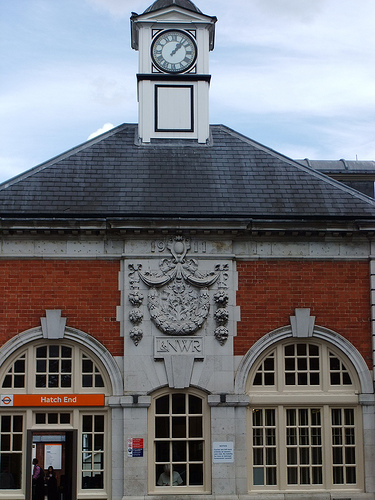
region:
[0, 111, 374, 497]
Red brick building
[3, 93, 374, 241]
Black tile roof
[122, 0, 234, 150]
White clock tower trimmed in black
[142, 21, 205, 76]
Clock face in the tower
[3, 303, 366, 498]
Arched windows trimmed in stone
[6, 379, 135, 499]
Entry way surrounded by glass windows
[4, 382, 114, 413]
Orange sign above the entrance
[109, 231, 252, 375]
Stone/concrete sculpture on the building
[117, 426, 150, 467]
Red, black, and white sign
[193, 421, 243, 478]
White sign on the building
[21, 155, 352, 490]
an old brick building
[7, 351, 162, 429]
an orange sign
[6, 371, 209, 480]
an orange and white sign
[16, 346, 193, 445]
a hatch end sign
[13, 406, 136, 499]
a door in a building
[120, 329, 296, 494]
a window on a building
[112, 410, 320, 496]
signs on a building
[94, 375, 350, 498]
signs on the side of a window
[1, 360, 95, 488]
a sign above the door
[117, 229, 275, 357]
decoration on the building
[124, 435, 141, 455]
red, white and blue sign to the right of the door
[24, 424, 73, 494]
doorway to the building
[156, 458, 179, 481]
person sitting in the center window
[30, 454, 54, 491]
two people standing in the doorway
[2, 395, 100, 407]
orange sign above the door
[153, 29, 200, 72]
clock on the top of the building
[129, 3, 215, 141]
clock tower on top of the building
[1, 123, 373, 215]
black shingle rood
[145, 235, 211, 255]
year 1911 carved into the side of building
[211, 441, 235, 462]
white sign to the right of the center window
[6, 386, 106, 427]
a hatch end sign on the building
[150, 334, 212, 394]
a nwr sign on the building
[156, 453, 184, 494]
a old lady standing in the window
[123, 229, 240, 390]
old cement signage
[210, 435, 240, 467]
a white sign on the building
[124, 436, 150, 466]
a red, white and blue sign on the building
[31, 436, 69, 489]
a group of people inside the building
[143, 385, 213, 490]
a small middle window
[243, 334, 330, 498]
a large window on the right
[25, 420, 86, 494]
a doorway in the middle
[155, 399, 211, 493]
window with many panes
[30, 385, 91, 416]
orange and white sign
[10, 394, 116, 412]
orange and white sign over door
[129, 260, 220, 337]
decorative stone above window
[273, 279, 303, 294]
building is of red brick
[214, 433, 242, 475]
white sign next to door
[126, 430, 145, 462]
red white and blue sign by window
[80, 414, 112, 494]
smaller window by door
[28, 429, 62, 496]
people standing under shelter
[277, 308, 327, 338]
decoration on arch above window